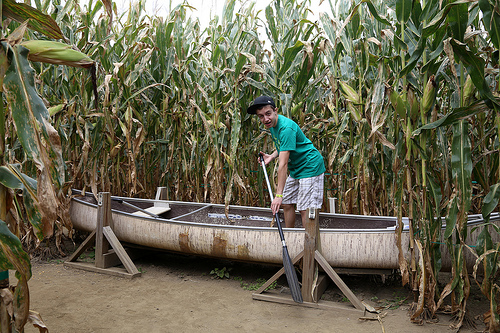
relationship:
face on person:
[255, 103, 292, 130] [237, 77, 342, 241]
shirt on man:
[266, 122, 323, 174] [223, 65, 335, 240]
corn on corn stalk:
[13, 40, 94, 68] [3, 0, 95, 326]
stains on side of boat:
[177, 230, 252, 257] [68, 187, 498, 269]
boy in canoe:
[245, 97, 324, 230] [60, 167, 449, 254]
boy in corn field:
[245, 97, 324, 230] [1, 0, 500, 333]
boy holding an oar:
[245, 97, 324, 230] [258, 152, 301, 304]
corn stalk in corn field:
[3, 0, 99, 332] [1, 0, 500, 333]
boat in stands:
[68, 187, 498, 269] [80, 193, 139, 278]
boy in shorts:
[245, 97, 324, 230] [233, 155, 356, 214]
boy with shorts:
[245, 92, 332, 229] [277, 175, 327, 211]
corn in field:
[13, 40, 94, 68] [284, 40, 465, 198]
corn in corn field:
[13, 40, 94, 68] [1, 0, 500, 333]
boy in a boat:
[245, 97, 324, 230] [68, 187, 498, 269]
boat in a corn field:
[68, 187, 498, 269] [1, 0, 498, 330]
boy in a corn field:
[245, 97, 324, 230] [1, 0, 498, 330]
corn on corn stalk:
[13, 35, 95, 70] [3, 0, 95, 326]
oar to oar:
[258, 152, 301, 304] [33, 135, 498, 319]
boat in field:
[68, 187, 498, 269] [8, 0, 485, 317]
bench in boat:
[134, 202, 169, 218] [68, 187, 498, 269]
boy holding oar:
[245, 97, 324, 230] [258, 152, 301, 304]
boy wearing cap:
[245, 97, 324, 230] [246, 96, 275, 110]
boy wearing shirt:
[245, 97, 324, 230] [270, 106, 329, 178]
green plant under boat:
[204, 264, 229, 276] [68, 187, 498, 269]